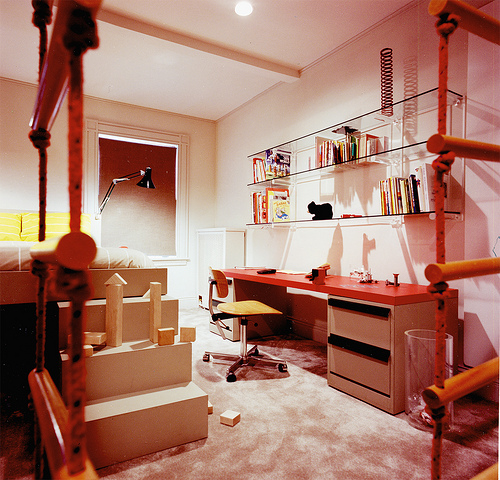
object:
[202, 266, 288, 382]
chair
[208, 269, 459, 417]
desk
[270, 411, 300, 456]
carpet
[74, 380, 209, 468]
steps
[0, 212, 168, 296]
bed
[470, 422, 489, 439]
shadow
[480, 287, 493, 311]
wall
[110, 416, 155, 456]
block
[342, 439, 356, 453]
floor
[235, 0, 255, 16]
light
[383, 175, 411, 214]
books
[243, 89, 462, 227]
shelf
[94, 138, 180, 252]
doorway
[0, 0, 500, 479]
room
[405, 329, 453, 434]
dust bin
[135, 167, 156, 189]
lamp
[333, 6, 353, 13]
ceiling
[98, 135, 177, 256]
window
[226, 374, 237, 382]
wheel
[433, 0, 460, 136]
bar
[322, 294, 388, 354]
drawers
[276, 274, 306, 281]
surface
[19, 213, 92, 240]
pillow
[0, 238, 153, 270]
mattress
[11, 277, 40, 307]
cabinet